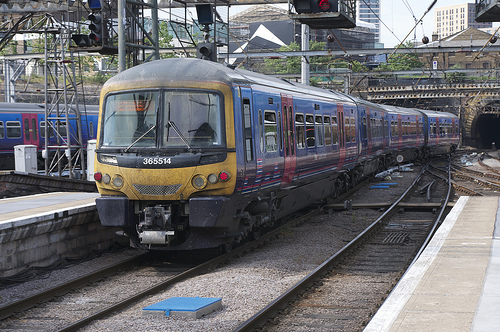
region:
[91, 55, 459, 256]
a train is on the tracks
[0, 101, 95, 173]
a train is on the next tracks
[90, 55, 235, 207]
the engine has a yellow front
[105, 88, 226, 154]
the windows have windshield wipers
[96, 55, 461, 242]
the engine is pulling three passenger cars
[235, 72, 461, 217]
the sides of the train are blue and red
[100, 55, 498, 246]
the train came out of a tunnel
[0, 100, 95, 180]
the next train is blue with red doors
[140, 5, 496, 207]
tall buildings are in the background of the train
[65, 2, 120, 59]
a traffic signal is above the tracks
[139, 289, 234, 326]
blue object on track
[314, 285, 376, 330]
small thin lines on the track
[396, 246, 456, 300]
white edge of the platform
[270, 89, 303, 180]
red door on the train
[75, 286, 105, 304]
small white spot on the train tracks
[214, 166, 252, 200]
red circular light on front of train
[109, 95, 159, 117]
reflection of red light in train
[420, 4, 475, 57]
square building in the background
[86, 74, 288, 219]
dirty yellow front of train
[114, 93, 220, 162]
windshield wipers on front of train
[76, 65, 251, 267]
train face is yellow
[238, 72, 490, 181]
train car is blue and red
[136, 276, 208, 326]
blue box on tracks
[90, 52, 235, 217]
the front of the train is painted yellow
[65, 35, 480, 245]
train on the tracks